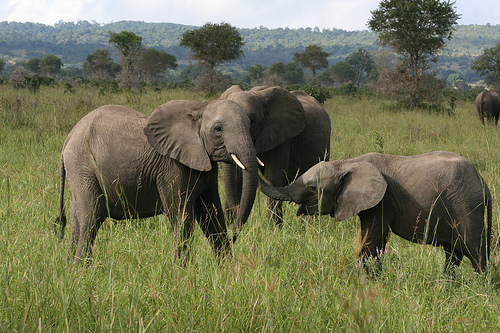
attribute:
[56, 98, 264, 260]
elephant — huge, gray, larger, looking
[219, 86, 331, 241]
elephant — huge, gray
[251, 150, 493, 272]
elephant — huge, young, reaching, smallest, gray, small, smaller, looking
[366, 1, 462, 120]
tree — huge, round, green, tall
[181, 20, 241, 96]
tree — huge, round, green, tall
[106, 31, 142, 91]
tree — huge, green, tall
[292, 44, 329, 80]
tree — huge, green, tall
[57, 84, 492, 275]
elephants — adults, young, three, gray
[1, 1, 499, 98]
forest — green, brown, many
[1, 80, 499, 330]
grasslands — tall, thin, high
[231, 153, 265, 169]
tusks — ivory, long, white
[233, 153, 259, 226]
trunk — curved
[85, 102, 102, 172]
indentation — round, bony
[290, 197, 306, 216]
mouth — open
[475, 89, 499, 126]
elephant — alone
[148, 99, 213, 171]
ear — gray, big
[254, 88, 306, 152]
ear — gray, big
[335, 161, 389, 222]
ear — gray, small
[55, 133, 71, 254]
tail — gray, long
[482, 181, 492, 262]
tail — gray, long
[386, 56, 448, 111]
bottom — dry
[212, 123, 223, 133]
eye — black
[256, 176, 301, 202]
trunk — touching